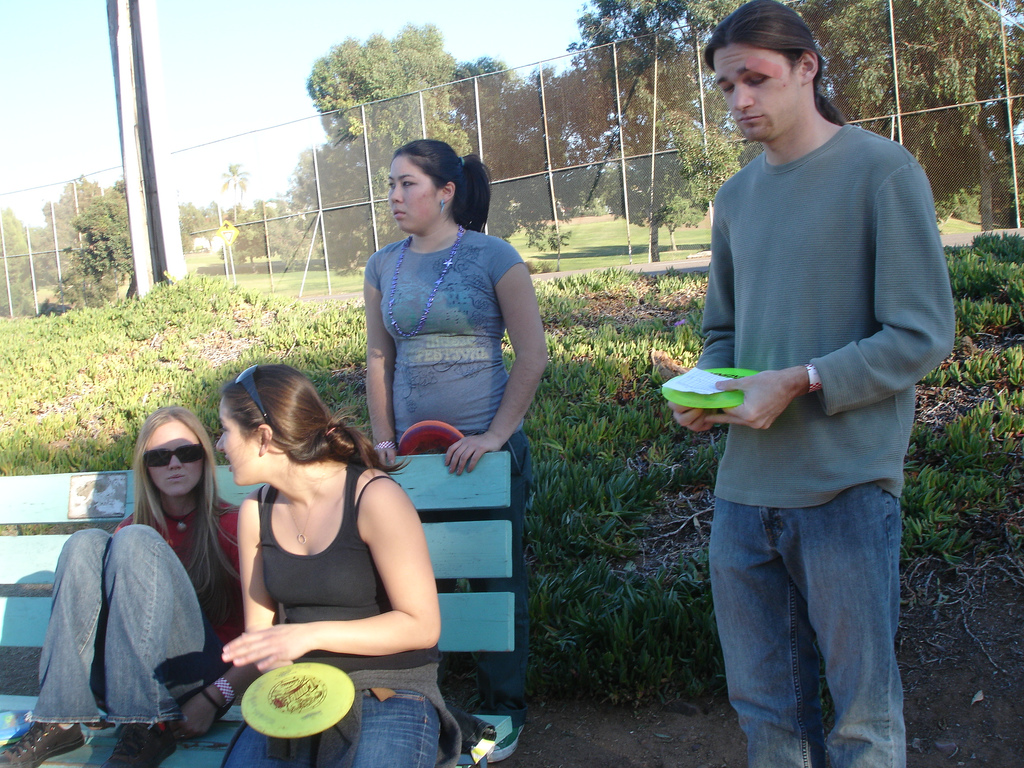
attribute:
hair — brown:
[394, 132, 492, 232]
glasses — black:
[145, 439, 200, 471]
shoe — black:
[106, 718, 182, 766]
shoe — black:
[2, 715, 88, 766]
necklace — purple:
[384, 225, 464, 342]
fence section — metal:
[612, 19, 707, 157]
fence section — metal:
[550, 155, 631, 272]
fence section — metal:
[782, 0, 901, 124]